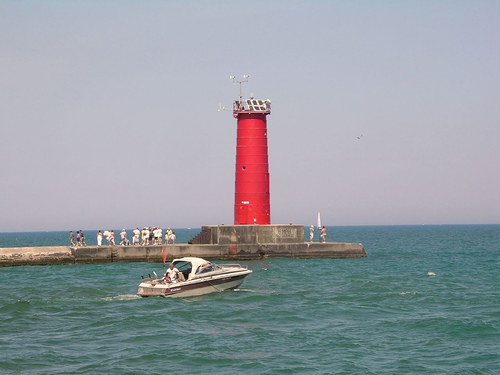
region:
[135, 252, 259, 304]
White boat on water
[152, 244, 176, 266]
Red flag on white boat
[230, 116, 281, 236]
Red tower on pier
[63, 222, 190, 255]
People standing on pier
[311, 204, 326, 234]
White object in distance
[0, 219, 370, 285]
Concrete pier on water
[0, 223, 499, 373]
Blue body of water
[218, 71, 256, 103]
Lights on top of tower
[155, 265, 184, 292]
People in white boat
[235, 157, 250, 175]
Hole on side of tower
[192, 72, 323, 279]
red lighthouse on cement deck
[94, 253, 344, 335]
person riding in motorboat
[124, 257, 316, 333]
motorboat in the water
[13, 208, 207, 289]
people on the cement pier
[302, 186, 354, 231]
sailboat with white sail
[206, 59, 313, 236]
lights on top of lighthouse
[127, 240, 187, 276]
sign in the water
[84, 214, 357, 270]
cement deck on cement pier in water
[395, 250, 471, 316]
white buoy in water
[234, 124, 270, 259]
person walking on deck next to lighthouse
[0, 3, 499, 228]
Sky is gray and hazy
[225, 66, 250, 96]
Lighthouse lamps for nightime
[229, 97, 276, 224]
Lighthouse is red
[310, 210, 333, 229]
A white sailboat in the distance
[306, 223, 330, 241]
two people standing together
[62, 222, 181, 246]
Groups of people stand on the path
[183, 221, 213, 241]
stairs leading to lighthouse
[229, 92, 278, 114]
important part of structure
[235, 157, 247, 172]
black circle on the lighthouse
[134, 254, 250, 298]
Person rides in a boat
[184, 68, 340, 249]
The lighthouse is red.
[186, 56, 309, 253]
There are stairs leading up to the lighthouse.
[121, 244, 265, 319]
The boat is in the water.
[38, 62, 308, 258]
People standing around the lighthouse.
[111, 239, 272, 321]
The boat is brown and white.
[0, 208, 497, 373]
The water is choppy.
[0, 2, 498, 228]
The sky is blue.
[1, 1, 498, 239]
The sky is cloudless.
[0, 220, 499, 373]
The water is wavy.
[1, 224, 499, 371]
The water is buoyant.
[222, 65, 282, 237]
a lighthouse on a dock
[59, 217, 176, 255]
a group of people on a dock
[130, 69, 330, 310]
a boat near a lighthouse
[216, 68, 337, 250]
two people in front a lighthouse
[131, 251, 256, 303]
a couple in a boat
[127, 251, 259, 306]
boat is white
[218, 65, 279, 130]
two lights on a lighthouse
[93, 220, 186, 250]
people wearing white tops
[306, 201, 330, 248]
a boat with a white sail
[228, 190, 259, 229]
door of a lighthouse